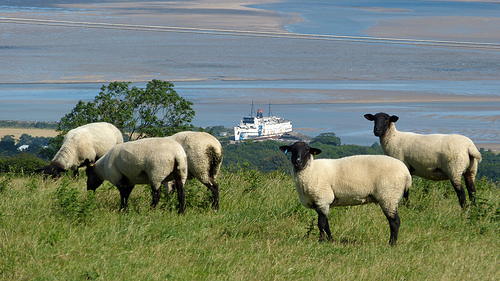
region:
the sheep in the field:
[31, 106, 489, 257]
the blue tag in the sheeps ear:
[278, 146, 289, 158]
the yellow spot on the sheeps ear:
[87, 158, 96, 168]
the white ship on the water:
[227, 93, 294, 141]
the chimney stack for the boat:
[255, 103, 261, 120]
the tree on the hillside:
[55, 72, 197, 125]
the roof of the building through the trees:
[13, 141, 48, 156]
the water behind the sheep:
[247, 6, 499, 96]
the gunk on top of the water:
[2, 1, 322, 78]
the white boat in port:
[233, 98, 298, 142]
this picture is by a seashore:
[11, 17, 477, 224]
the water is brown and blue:
[131, 5, 419, 147]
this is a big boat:
[224, 97, 352, 191]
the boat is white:
[218, 100, 309, 135]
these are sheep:
[50, 72, 444, 253]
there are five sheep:
[12, 99, 480, 260]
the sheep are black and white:
[272, 126, 436, 209]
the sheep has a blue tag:
[275, 142, 298, 152]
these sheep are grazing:
[80, 79, 251, 182]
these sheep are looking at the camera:
[283, 103, 425, 259]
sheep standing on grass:
[57, 83, 478, 274]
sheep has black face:
[367, 108, 398, 148]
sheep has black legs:
[281, 224, 405, 259]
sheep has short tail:
[375, 160, 412, 218]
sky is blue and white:
[262, 3, 410, 114]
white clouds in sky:
[257, 7, 498, 108]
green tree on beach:
[88, 87, 192, 154]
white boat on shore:
[221, 84, 296, 156]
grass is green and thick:
[50, 194, 168, 274]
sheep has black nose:
[282, 134, 310, 169]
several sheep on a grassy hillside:
[33, 78, 492, 257]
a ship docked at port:
[225, 92, 327, 142]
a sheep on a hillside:
[275, 135, 415, 245]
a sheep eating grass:
[25, 125, 80, 185]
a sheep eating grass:
[76, 135, 182, 210]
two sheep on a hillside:
[280, 108, 481, 248]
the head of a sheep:
[276, 136, 321, 171]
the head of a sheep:
[359, 106, 404, 141]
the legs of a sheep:
[305, 199, 409, 249]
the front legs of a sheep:
[308, 203, 333, 243]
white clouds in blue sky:
[22, 38, 89, 90]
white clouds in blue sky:
[74, 12, 121, 40]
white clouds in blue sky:
[312, 26, 350, 64]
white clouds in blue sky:
[240, 41, 295, 72]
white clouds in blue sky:
[348, 61, 433, 96]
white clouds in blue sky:
[238, 25, 286, 62]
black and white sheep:
[35, 112, 120, 180]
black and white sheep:
[104, 116, 215, 217]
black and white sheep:
[282, 143, 422, 231]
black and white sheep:
[345, 98, 496, 196]